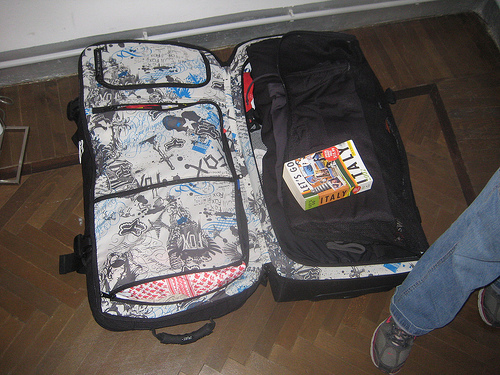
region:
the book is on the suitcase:
[278, 127, 380, 211]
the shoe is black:
[365, 304, 411, 374]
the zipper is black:
[99, 78, 206, 91]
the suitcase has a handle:
[142, 325, 238, 347]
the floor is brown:
[8, 204, 54, 343]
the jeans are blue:
[432, 226, 484, 308]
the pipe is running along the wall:
[11, 52, 54, 67]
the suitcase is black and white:
[52, 26, 414, 369]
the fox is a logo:
[115, 213, 145, 242]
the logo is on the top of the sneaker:
[380, 344, 400, 359]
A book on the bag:
[283, 143, 371, 210]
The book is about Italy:
[284, 139, 374, 212]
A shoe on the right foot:
[372, 310, 412, 370]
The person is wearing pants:
[388, 168, 498, 335]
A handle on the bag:
[154, 318, 216, 342]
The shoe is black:
[371, 315, 413, 369]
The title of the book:
[336, 147, 368, 182]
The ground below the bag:
[0, 13, 497, 374]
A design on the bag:
[77, 50, 260, 317]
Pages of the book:
[281, 166, 303, 205]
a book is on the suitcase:
[282, 135, 374, 207]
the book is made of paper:
[281, 140, 377, 210]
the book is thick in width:
[281, 139, 380, 209]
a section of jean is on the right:
[386, 154, 498, 330]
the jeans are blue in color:
[393, 164, 497, 324]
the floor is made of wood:
[0, 7, 499, 372]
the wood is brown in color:
[3, 11, 498, 372]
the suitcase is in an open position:
[76, 38, 431, 331]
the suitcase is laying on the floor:
[73, 30, 424, 330]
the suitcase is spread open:
[70, 31, 433, 339]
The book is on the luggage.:
[273, 144, 383, 209]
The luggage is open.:
[88, 37, 432, 319]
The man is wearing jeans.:
[392, 205, 489, 335]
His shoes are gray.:
[361, 318, 413, 370]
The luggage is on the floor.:
[51, 30, 446, 330]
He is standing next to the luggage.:
[44, 23, 446, 330]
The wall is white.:
[7, 5, 243, 43]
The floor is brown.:
[5, 89, 93, 356]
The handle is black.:
[58, 240, 90, 275]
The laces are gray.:
[386, 327, 404, 352]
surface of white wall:
[0, 0, 307, 47]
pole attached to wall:
[0, 2, 427, 82]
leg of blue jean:
[388, 168, 497, 334]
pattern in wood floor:
[5, 18, 495, 370]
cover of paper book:
[281, 140, 372, 207]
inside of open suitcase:
[74, 26, 423, 344]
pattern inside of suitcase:
[89, 43, 251, 300]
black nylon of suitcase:
[256, 30, 421, 265]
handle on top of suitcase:
[151, 319, 218, 344]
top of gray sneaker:
[369, 319, 411, 371]